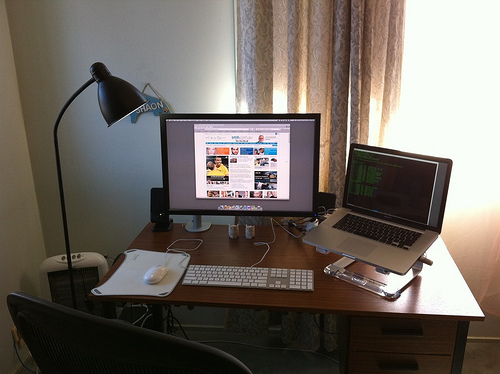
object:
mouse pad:
[92, 247, 192, 296]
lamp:
[53, 64, 144, 307]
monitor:
[157, 109, 326, 215]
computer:
[300, 143, 458, 276]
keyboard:
[174, 264, 321, 292]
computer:
[159, 111, 322, 291]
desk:
[81, 222, 485, 319]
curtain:
[236, 0, 403, 226]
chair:
[2, 288, 253, 373]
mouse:
[143, 262, 169, 286]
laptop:
[299, 134, 449, 271]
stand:
[320, 251, 421, 303]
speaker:
[148, 186, 173, 233]